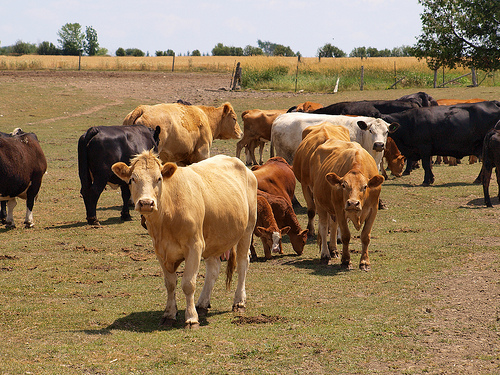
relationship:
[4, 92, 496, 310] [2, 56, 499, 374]
cows in pasture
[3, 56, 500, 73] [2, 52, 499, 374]
wheat in field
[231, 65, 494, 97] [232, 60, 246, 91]
fence has posts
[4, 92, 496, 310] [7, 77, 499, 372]
cows eat grass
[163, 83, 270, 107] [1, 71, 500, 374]
manure on ground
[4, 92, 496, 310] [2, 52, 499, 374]
cows in field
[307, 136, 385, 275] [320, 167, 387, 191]
cow has ears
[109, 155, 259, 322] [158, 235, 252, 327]
cow has legs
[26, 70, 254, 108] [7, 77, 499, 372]
dirt on grass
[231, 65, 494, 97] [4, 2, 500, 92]
fence in background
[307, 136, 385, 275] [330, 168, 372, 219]
cow has head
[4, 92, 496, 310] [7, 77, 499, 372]
cows on grass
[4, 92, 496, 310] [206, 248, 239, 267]
cows have utters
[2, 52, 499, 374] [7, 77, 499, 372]
field of grass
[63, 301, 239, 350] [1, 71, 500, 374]
shadow on ground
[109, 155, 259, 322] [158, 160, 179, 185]
cow has ear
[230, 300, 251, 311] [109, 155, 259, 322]
hoof of cow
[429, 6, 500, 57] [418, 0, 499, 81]
leaves on tree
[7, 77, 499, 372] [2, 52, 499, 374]
grass in field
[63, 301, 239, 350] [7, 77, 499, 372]
shadow on grass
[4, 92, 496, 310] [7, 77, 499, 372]
cows in grass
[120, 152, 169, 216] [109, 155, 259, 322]
face of cow